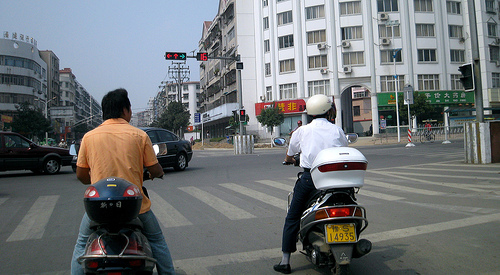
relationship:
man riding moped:
[74, 88, 166, 271] [77, 229, 157, 271]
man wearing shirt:
[74, 88, 166, 271] [74, 119, 158, 214]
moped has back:
[77, 229, 157, 271] [92, 236, 142, 270]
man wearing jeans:
[74, 88, 166, 271] [69, 208, 175, 271]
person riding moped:
[272, 93, 350, 270] [297, 186, 373, 268]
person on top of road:
[272, 93, 350, 270] [6, 139, 495, 269]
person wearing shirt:
[272, 93, 350, 270] [286, 118, 351, 172]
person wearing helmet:
[272, 93, 350, 270] [305, 93, 334, 117]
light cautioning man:
[166, 53, 189, 60] [74, 88, 166, 271]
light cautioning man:
[197, 53, 210, 61] [69, 119, 160, 217]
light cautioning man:
[236, 62, 244, 70] [74, 88, 166, 271]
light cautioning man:
[239, 108, 247, 123] [74, 88, 166, 271]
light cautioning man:
[459, 64, 477, 94] [74, 88, 166, 271]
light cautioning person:
[166, 53, 189, 60] [272, 93, 350, 270]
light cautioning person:
[197, 53, 210, 61] [272, 93, 350, 270]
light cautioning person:
[239, 108, 247, 123] [272, 93, 350, 270]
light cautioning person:
[459, 64, 477, 94] [272, 93, 350, 270]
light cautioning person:
[236, 62, 244, 70] [272, 93, 350, 270]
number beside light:
[196, 52, 210, 60] [166, 53, 189, 60]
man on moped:
[74, 88, 166, 271] [77, 229, 157, 271]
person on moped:
[272, 93, 350, 270] [297, 186, 373, 268]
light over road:
[166, 53, 189, 60] [6, 139, 495, 269]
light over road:
[197, 53, 210, 61] [6, 139, 495, 269]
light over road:
[236, 62, 244, 70] [6, 139, 495, 269]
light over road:
[239, 108, 247, 123] [6, 139, 495, 269]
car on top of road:
[5, 131, 71, 176] [6, 139, 495, 269]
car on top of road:
[141, 126, 194, 171] [6, 139, 495, 269]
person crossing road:
[272, 93, 350, 270] [6, 139, 495, 269]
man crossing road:
[74, 88, 166, 271] [6, 139, 495, 269]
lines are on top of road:
[9, 157, 495, 270] [6, 139, 495, 269]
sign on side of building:
[378, 91, 477, 106] [235, 3, 479, 140]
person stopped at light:
[272, 93, 350, 270] [166, 53, 189, 60]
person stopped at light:
[272, 93, 350, 270] [197, 53, 210, 61]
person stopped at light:
[272, 93, 350, 270] [236, 62, 244, 70]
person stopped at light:
[272, 93, 350, 270] [239, 108, 247, 123]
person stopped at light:
[272, 93, 350, 270] [459, 64, 477, 94]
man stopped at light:
[74, 88, 166, 271] [197, 53, 210, 61]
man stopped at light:
[74, 88, 166, 271] [236, 62, 244, 70]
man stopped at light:
[74, 88, 166, 271] [239, 108, 247, 123]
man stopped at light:
[74, 88, 166, 271] [459, 64, 477, 94]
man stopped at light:
[74, 88, 166, 271] [166, 53, 189, 60]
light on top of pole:
[166, 53, 189, 60] [233, 49, 251, 135]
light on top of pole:
[197, 53, 210, 61] [233, 49, 251, 135]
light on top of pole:
[236, 62, 244, 70] [233, 49, 251, 135]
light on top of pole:
[239, 108, 247, 123] [233, 49, 251, 135]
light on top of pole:
[459, 64, 477, 94] [466, 3, 486, 121]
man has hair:
[74, 88, 166, 271] [102, 89, 132, 121]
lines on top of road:
[9, 157, 495, 270] [6, 139, 495, 269]